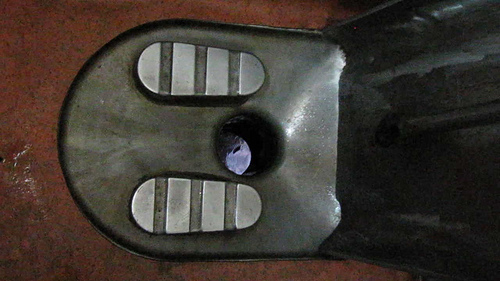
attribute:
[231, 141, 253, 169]
water — shining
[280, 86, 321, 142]
light — reflecting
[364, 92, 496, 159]
pipe — black